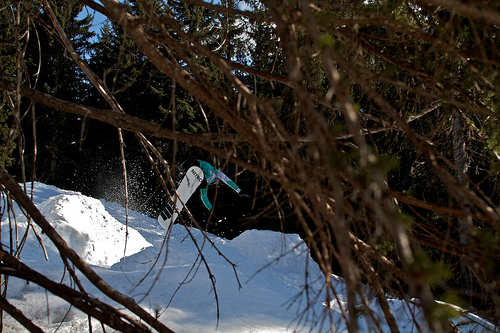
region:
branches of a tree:
[358, 150, 384, 188]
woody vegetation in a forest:
[348, 152, 358, 204]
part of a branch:
[372, 192, 390, 232]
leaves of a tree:
[11, 121, 20, 169]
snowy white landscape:
[246, 250, 263, 285]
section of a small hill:
[87, 210, 99, 225]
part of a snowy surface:
[98, 220, 139, 250]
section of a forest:
[99, 36, 124, 58]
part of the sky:
[93, 17, 96, 24]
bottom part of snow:
[243, 284, 270, 324]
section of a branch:
[191, 90, 213, 97]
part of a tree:
[433, 156, 445, 171]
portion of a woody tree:
[274, 144, 299, 171]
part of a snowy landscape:
[246, 275, 261, 307]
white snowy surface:
[238, 300, 245, 317]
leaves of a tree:
[431, 42, 441, 84]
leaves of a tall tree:
[87, 36, 102, 61]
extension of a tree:
[81, 112, 138, 121]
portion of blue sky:
[94, 20, 103, 27]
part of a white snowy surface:
[253, 305, 276, 317]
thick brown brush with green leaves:
[292, 2, 498, 322]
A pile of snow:
[24, 167, 159, 290]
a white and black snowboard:
[152, 166, 205, 239]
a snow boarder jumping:
[147, 142, 264, 269]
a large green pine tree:
[91, 21, 128, 204]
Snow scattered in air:
[94, 147, 168, 236]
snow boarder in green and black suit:
[178, 151, 245, 225]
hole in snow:
[3, 294, 100, 331]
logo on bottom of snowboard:
[181, 164, 206, 191]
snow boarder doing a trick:
[41, 94, 278, 295]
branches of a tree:
[368, 191, 387, 206]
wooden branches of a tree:
[288, 174, 319, 210]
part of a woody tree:
[396, 157, 421, 200]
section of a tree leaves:
[261, 111, 303, 131]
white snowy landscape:
[252, 280, 264, 297]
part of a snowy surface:
[78, 199, 135, 239]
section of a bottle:
[189, 177, 201, 185]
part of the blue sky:
[96, 30, 102, 36]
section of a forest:
[107, 73, 157, 110]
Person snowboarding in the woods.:
[138, 136, 253, 256]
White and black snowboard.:
[145, 156, 210, 235]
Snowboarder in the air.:
[150, 145, 249, 248]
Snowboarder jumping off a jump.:
[20, 137, 257, 275]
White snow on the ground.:
[20, 171, 317, 331]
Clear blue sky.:
[70, 1, 128, 71]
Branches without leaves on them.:
[81, 7, 451, 242]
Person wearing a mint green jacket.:
[186, 149, 250, 223]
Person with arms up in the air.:
[153, 141, 255, 245]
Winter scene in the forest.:
[9, 6, 481, 325]